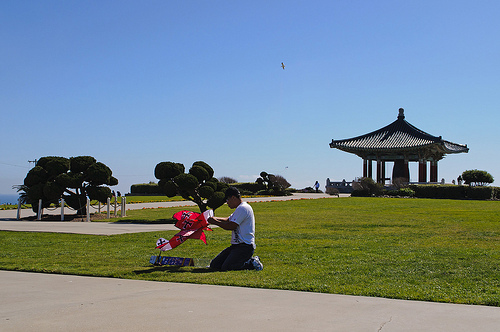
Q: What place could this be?
A: It is a park.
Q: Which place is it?
A: It is a park.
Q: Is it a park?
A: Yes, it is a park.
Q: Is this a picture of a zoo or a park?
A: It is showing a park.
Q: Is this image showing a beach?
A: No, the picture is showing a park.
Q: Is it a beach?
A: No, it is a park.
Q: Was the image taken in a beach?
A: No, the picture was taken in a park.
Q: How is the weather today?
A: It is clear.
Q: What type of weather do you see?
A: It is clear.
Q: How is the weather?
A: It is clear.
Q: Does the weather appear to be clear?
A: Yes, it is clear.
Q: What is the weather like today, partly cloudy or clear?
A: It is clear.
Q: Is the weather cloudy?
A: No, it is clear.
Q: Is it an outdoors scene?
A: Yes, it is outdoors.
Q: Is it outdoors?
A: Yes, it is outdoors.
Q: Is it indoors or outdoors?
A: It is outdoors.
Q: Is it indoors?
A: No, it is outdoors.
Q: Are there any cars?
A: No, there are no cars.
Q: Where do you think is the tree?
A: The tree is in the park.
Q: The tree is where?
A: The tree is in the park.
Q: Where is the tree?
A: The tree is in the park.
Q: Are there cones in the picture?
A: No, there are no cones.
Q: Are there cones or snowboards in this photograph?
A: No, there are no cones or snowboards.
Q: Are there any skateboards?
A: No, there are no skateboards.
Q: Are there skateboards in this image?
A: No, there are no skateboards.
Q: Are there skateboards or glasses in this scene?
A: No, there are no skateboards or glasses.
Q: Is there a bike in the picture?
A: No, there are no bikes.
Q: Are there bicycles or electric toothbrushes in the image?
A: No, there are no bicycles or electric toothbrushes.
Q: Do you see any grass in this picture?
A: Yes, there is grass.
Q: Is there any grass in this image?
A: Yes, there is grass.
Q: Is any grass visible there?
A: Yes, there is grass.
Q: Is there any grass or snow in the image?
A: Yes, there is grass.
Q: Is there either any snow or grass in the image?
A: Yes, there is grass.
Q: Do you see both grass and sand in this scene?
A: No, there is grass but no sand.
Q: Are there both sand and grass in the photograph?
A: No, there is grass but no sand.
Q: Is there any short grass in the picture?
A: Yes, there is short grass.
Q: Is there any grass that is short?
A: Yes, there is grass that is short.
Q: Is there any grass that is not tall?
A: Yes, there is short grass.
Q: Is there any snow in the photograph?
A: No, there is no snow.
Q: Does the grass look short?
A: Yes, the grass is short.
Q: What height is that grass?
A: The grass is short.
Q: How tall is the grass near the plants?
A: The grass is short.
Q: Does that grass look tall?
A: No, the grass is short.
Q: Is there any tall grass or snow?
A: No, there is grass but it is short.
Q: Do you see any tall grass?
A: No, there is grass but it is short.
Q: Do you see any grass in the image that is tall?
A: No, there is grass but it is short.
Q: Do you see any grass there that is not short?
A: No, there is grass but it is short.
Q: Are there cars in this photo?
A: No, there are no cars.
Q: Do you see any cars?
A: No, there are no cars.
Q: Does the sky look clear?
A: Yes, the sky is clear.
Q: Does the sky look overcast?
A: No, the sky is clear.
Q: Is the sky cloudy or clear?
A: The sky is clear.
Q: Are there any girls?
A: No, there are no girls.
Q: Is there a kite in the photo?
A: Yes, there is a kite.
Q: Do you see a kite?
A: Yes, there is a kite.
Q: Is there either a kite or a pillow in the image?
A: Yes, there is a kite.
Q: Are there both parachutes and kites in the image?
A: No, there is a kite but no parachutes.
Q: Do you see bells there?
A: No, there are no bells.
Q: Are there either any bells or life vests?
A: No, there are no bells or life vests.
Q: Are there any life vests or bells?
A: No, there are no bells or life vests.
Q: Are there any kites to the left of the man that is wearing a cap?
A: Yes, there is a kite to the left of the man.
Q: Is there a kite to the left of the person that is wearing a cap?
A: Yes, there is a kite to the left of the man.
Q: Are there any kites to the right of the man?
A: No, the kite is to the left of the man.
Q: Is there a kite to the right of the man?
A: No, the kite is to the left of the man.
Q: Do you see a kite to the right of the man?
A: No, the kite is to the left of the man.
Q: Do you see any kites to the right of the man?
A: No, the kite is to the left of the man.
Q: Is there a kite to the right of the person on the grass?
A: No, the kite is to the left of the man.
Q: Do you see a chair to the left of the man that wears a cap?
A: No, there is a kite to the left of the man.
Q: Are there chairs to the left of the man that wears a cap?
A: No, there is a kite to the left of the man.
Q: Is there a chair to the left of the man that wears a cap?
A: No, there is a kite to the left of the man.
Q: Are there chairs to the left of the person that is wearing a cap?
A: No, there is a kite to the left of the man.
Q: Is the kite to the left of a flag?
A: No, the kite is to the left of the man.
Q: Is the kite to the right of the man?
A: No, the kite is to the left of the man.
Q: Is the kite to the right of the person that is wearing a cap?
A: No, the kite is to the left of the man.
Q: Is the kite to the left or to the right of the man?
A: The kite is to the left of the man.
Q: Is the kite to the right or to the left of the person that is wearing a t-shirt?
A: The kite is to the left of the man.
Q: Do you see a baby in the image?
A: No, there are no babies.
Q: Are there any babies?
A: No, there are no babies.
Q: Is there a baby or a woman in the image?
A: No, there are no babies or women.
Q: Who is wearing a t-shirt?
A: The man is wearing a t-shirt.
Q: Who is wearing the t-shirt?
A: The man is wearing a t-shirt.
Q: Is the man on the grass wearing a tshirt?
A: Yes, the man is wearing a tshirt.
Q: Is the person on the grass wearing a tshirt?
A: Yes, the man is wearing a tshirt.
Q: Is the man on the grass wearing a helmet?
A: No, the man is wearing a tshirt.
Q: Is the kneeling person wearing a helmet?
A: No, the man is wearing a tshirt.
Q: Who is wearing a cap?
A: The man is wearing a cap.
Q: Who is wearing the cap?
A: The man is wearing a cap.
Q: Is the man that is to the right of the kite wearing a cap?
A: Yes, the man is wearing a cap.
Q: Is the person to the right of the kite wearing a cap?
A: Yes, the man is wearing a cap.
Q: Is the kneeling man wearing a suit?
A: No, the man is wearing a cap.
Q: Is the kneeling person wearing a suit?
A: No, the man is wearing a cap.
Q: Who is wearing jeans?
A: The man is wearing jeans.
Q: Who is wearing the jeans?
A: The man is wearing jeans.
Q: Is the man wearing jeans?
A: Yes, the man is wearing jeans.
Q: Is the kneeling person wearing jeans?
A: Yes, the man is wearing jeans.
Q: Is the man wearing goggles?
A: No, the man is wearing jeans.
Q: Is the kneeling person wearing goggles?
A: No, the man is wearing jeans.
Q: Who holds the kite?
A: The man holds the kite.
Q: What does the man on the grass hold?
A: The man holds the kite.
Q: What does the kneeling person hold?
A: The man holds the kite.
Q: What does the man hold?
A: The man holds the kite.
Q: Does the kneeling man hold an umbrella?
A: No, the man holds the kite.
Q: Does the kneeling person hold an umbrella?
A: No, the man holds the kite.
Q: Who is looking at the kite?
A: The man is looking at the kite.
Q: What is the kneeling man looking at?
A: The man is looking at the kite.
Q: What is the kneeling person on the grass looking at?
A: The man is looking at the kite.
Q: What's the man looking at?
A: The man is looking at the kite.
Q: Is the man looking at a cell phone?
A: No, the man is looking at the kite.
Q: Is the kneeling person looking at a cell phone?
A: No, the man is looking at the kite.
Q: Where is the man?
A: The man is on the grass.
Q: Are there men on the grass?
A: Yes, there is a man on the grass.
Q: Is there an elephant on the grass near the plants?
A: No, there is a man on the grass.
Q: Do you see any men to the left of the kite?
A: No, the man is to the right of the kite.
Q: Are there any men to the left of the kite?
A: No, the man is to the right of the kite.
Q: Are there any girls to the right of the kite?
A: No, there is a man to the right of the kite.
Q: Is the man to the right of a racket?
A: No, the man is to the right of the kite.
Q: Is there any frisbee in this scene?
A: No, there are no frisbees.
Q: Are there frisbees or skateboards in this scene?
A: No, there are no frisbees or skateboards.